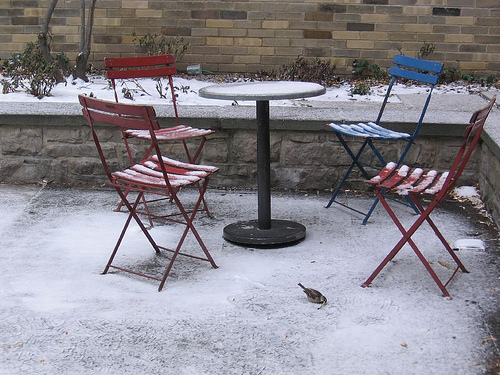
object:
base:
[224, 216, 311, 248]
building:
[5, 0, 496, 78]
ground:
[0, 181, 497, 373]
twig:
[315, 300, 327, 311]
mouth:
[320, 297, 327, 304]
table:
[198, 79, 325, 247]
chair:
[77, 93, 222, 291]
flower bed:
[0, 70, 495, 97]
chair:
[348, 77, 499, 308]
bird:
[297, 278, 331, 310]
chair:
[302, 27, 456, 222]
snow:
[0, 184, 499, 372]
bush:
[0, 28, 66, 98]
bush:
[125, 27, 190, 100]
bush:
[304, 45, 342, 88]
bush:
[346, 80, 374, 96]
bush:
[391, 42, 434, 84]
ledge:
[3, 78, 195, 120]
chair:
[95, 51, 217, 215]